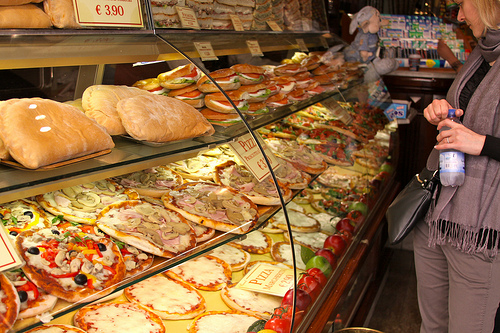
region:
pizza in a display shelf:
[16, 221, 123, 302]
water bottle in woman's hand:
[431, 82, 468, 206]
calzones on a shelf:
[0, 74, 211, 170]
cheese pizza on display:
[132, 271, 239, 331]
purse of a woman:
[381, 169, 433, 249]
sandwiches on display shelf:
[200, 64, 304, 122]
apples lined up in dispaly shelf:
[281, 235, 346, 330]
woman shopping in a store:
[347, 7, 399, 107]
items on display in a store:
[386, 9, 458, 85]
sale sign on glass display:
[191, 34, 224, 67]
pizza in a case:
[17, 225, 115, 282]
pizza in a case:
[117, 201, 183, 261]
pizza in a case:
[171, 177, 252, 227]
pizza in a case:
[91, 302, 152, 327]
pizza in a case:
[198, 303, 238, 329]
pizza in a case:
[160, 280, 195, 320]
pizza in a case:
[201, 255, 226, 291]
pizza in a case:
[210, 308, 251, 329]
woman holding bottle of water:
[398, 3, 490, 329]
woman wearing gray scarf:
[390, 7, 499, 319]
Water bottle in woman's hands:
[436, 106, 464, 188]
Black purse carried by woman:
[382, 163, 438, 245]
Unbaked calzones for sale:
[2, 80, 215, 179]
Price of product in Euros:
[87, 4, 124, 16]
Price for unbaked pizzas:
[235, 261, 303, 297]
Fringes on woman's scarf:
[421, 219, 495, 261]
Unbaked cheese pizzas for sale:
[22, 205, 341, 332]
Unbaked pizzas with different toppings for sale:
[2, 97, 384, 328]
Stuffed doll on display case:
[344, 6, 394, 76]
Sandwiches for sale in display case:
[133, 53, 367, 126]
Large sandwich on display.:
[211, 65, 238, 94]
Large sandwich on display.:
[239, 63, 262, 83]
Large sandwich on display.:
[246, 83, 266, 100]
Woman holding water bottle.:
[433, 108, 480, 198]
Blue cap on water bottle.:
[444, 106, 461, 118]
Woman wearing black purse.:
[391, 145, 437, 225]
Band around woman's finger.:
[440, 132, 453, 149]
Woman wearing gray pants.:
[431, 248, 485, 327]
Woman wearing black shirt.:
[483, 125, 492, 143]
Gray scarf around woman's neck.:
[441, 65, 497, 142]